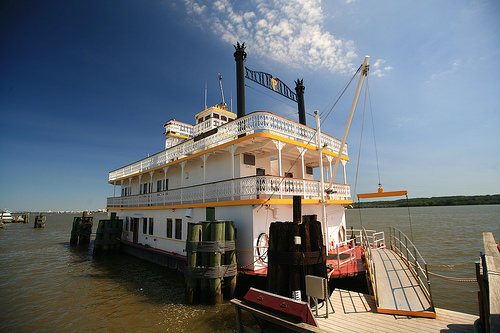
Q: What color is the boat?
A: Yellow and white.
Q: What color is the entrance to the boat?
A: Tan and gray.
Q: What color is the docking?
A: Brown.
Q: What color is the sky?
A: Blue.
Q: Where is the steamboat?
A: On the river.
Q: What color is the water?
A: Brown.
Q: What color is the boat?
A: White and yellow.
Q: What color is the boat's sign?
A: Black.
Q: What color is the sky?
A: Blue.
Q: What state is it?
A: North Carolina.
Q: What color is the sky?
A: Blue.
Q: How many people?
A: 0.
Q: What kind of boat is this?
A: Steamboat.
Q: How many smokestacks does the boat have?
A: Two.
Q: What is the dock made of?
A: Wood.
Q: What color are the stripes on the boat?
A: Orange.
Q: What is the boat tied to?
A: Dock.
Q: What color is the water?
A: Gray.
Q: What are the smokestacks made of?
A: Metal.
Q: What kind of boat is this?
A: A steamboat.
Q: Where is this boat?
A: On a river.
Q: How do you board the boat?
A: Using the ramp.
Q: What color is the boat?
A: White.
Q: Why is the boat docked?
A: To pick up passengers.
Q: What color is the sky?
A: Blue.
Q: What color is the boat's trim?
A: Yellow.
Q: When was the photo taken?
A: During the day.